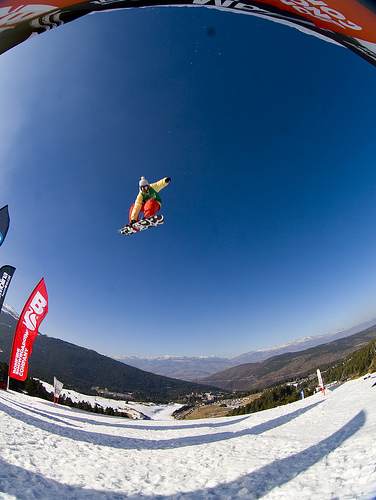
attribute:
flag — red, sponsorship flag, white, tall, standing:
[10, 266, 59, 388]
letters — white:
[22, 283, 50, 338]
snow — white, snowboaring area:
[3, 382, 373, 495]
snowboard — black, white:
[120, 213, 164, 234]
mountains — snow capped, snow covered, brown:
[12, 319, 372, 404]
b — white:
[28, 287, 52, 315]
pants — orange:
[127, 198, 167, 224]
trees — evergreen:
[19, 374, 140, 422]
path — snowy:
[3, 363, 223, 498]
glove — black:
[161, 172, 173, 186]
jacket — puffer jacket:
[129, 177, 188, 213]